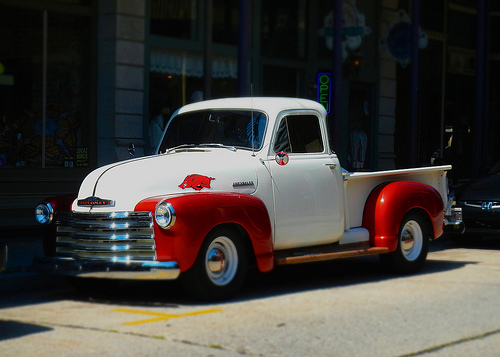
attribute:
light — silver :
[155, 200, 176, 229]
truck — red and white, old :
[34, 95, 453, 295]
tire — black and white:
[192, 216, 257, 296]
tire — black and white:
[392, 206, 432, 267]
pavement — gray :
[4, 219, 495, 355]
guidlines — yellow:
[97, 290, 227, 338]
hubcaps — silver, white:
[211, 240, 233, 281]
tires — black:
[187, 271, 216, 294]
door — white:
[267, 157, 361, 254]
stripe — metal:
[88, 154, 111, 203]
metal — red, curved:
[361, 186, 444, 237]